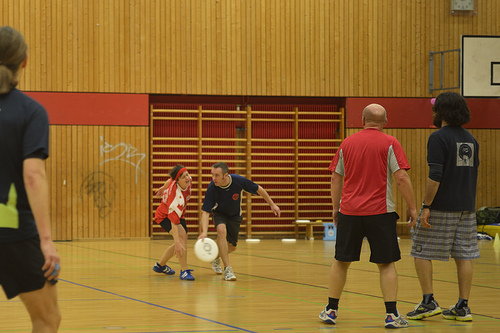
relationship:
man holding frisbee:
[191, 159, 286, 283] [193, 236, 220, 263]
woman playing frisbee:
[149, 163, 195, 284] [193, 236, 220, 263]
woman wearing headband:
[149, 163, 195, 284] [172, 165, 190, 180]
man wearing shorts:
[403, 91, 480, 324] [408, 204, 482, 264]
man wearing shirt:
[317, 103, 420, 332] [328, 124, 410, 215]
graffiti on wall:
[69, 131, 146, 224] [0, 0, 499, 243]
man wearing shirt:
[191, 159, 286, 283] [198, 174, 258, 220]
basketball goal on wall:
[457, 31, 499, 97] [0, 0, 499, 243]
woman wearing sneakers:
[149, 163, 195, 284] [149, 258, 201, 284]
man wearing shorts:
[317, 103, 420, 332] [330, 206, 403, 266]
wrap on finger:
[53, 263, 58, 276] [46, 260, 59, 285]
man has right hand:
[191, 159, 286, 283] [196, 229, 211, 245]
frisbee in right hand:
[193, 236, 220, 263] [196, 229, 211, 245]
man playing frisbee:
[191, 159, 286, 283] [193, 236, 220, 263]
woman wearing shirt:
[149, 163, 195, 284] [151, 184, 195, 225]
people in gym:
[0, 22, 474, 329] [1, 0, 499, 332]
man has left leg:
[403, 91, 480, 324] [407, 252, 442, 320]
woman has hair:
[149, 163, 195, 284] [165, 162, 186, 178]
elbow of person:
[25, 165, 44, 191] [0, 20, 62, 332]